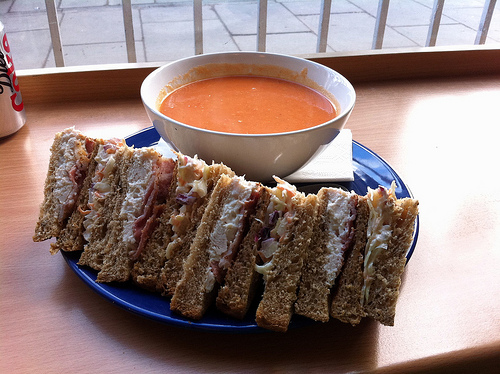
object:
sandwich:
[30, 124, 420, 333]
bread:
[364, 180, 420, 327]